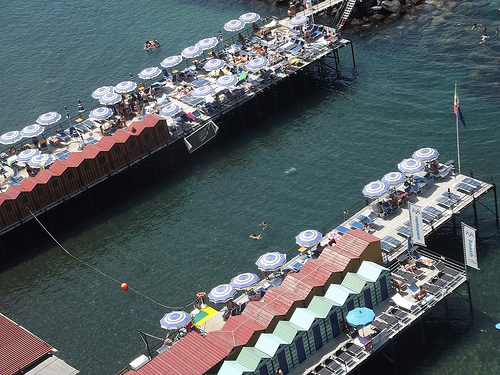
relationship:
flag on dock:
[454, 83, 467, 127] [319, 151, 499, 312]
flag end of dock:
[452, 80, 470, 127] [0, 12, 355, 236]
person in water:
[255, 217, 274, 229] [2, 5, 496, 374]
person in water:
[248, 228, 263, 243] [2, 5, 496, 374]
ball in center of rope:
[115, 282, 140, 301] [53, 244, 165, 316]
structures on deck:
[213, 255, 394, 373] [198, 240, 476, 374]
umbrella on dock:
[357, 179, 389, 199] [102, 140, 499, 372]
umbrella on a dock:
[254, 246, 287, 273] [102, 140, 499, 372]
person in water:
[140, 33, 161, 54] [1, 4, 171, 64]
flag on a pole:
[454, 83, 467, 127] [449, 82, 462, 172]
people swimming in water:
[452, 36, 493, 74] [336, 83, 478, 155]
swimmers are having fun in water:
[226, 217, 281, 249] [2, 5, 496, 374]